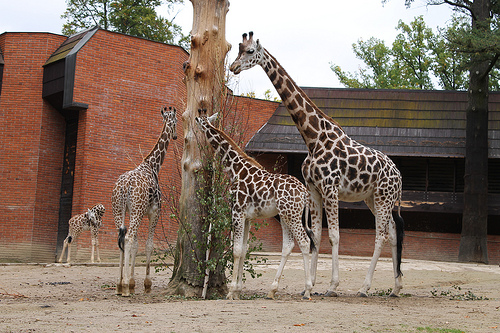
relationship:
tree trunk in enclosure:
[162, 1, 234, 296] [4, 28, 494, 329]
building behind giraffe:
[3, 29, 279, 266] [109, 108, 175, 299]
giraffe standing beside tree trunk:
[227, 32, 415, 300] [162, 1, 234, 296]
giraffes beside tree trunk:
[189, 109, 320, 298] [162, 1, 234, 296]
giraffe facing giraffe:
[109, 108, 175, 299] [227, 32, 415, 300]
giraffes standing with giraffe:
[189, 109, 320, 298] [227, 32, 415, 300]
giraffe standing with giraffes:
[227, 32, 415, 300] [189, 109, 320, 298]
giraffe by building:
[62, 204, 107, 265] [3, 29, 279, 266]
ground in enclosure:
[2, 241, 494, 332] [4, 28, 494, 329]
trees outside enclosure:
[58, 4, 498, 91] [4, 28, 494, 329]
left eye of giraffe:
[245, 46, 256, 56] [227, 32, 415, 300]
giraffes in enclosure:
[58, 31, 406, 298] [4, 28, 494, 329]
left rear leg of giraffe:
[362, 190, 393, 297] [227, 32, 415, 300]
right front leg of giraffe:
[303, 191, 326, 294] [227, 32, 415, 300]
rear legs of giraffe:
[59, 233, 79, 266] [62, 204, 107, 265]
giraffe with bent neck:
[62, 204, 107, 265] [93, 204, 110, 219]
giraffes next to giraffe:
[189, 109, 320, 298] [227, 32, 415, 300]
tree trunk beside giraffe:
[162, 1, 234, 296] [227, 32, 415, 300]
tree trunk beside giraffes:
[162, 1, 234, 296] [189, 109, 320, 298]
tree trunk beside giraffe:
[162, 1, 234, 296] [109, 108, 175, 299]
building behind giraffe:
[3, 29, 279, 266] [62, 204, 107, 265]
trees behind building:
[58, 4, 498, 91] [3, 29, 279, 266]